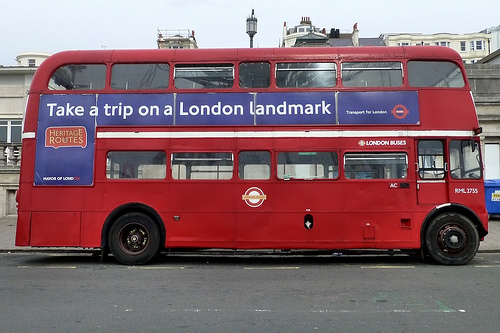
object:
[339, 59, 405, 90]
window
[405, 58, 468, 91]
window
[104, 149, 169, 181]
window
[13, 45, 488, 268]
bus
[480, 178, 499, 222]
garbage bin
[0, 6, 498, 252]
building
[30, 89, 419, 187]
advertisement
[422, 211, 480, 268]
wheel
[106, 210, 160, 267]
wheel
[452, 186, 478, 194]
serial number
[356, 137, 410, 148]
bus company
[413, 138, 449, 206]
door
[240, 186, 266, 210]
emblem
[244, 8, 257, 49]
light post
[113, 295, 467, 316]
markings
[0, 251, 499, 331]
road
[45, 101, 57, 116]
letter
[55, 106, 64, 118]
letter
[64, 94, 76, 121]
letter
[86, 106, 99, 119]
letter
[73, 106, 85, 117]
letter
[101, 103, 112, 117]
letter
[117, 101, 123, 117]
letter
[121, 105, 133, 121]
letter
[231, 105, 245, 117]
letter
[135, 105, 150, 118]
letter